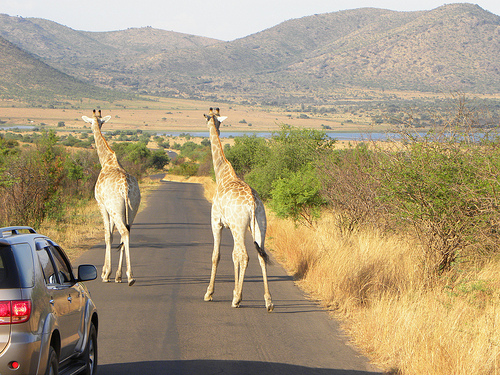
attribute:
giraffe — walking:
[67, 103, 159, 300]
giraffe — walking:
[182, 96, 302, 315]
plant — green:
[271, 155, 347, 227]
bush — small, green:
[262, 165, 321, 218]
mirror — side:
[74, 263, 99, 281]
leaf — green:
[280, 160, 291, 176]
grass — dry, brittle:
[383, 210, 464, 354]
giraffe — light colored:
[190, 99, 272, 319]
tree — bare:
[316, 158, 383, 243]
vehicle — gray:
[0, 213, 140, 368]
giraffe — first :
[200, 102, 274, 313]